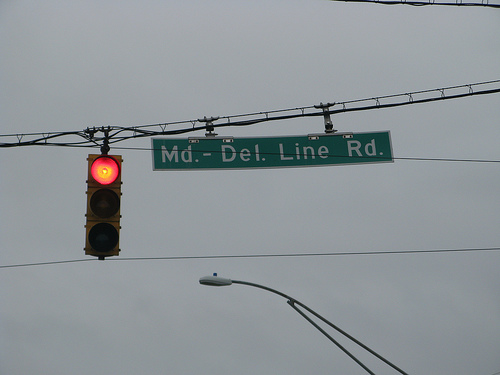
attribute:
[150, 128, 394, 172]
street sign — green, east coast road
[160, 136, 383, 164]
lettering — white, md.-del. line rd.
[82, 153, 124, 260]
traffic signal — red, indicating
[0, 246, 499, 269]
power line — power line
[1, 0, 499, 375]
sky — overcast, gray, dark grey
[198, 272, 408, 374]
street lamp — long, pictured, tall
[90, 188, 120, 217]
bulb — not lit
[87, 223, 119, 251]
bulb — not lit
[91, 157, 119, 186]
light — red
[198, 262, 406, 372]
street light — pictured